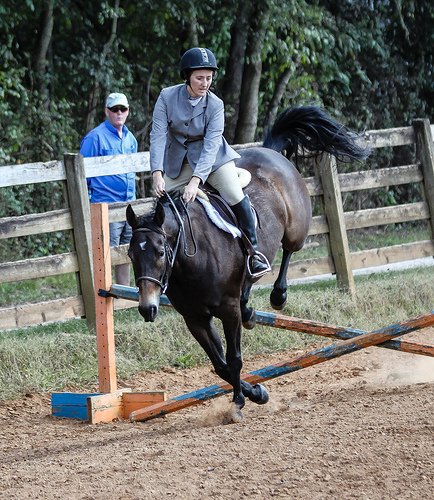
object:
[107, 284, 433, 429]
jump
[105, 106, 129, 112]
dark glasses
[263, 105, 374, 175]
tail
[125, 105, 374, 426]
zebra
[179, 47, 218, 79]
hat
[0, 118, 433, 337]
fence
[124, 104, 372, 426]
horse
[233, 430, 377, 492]
path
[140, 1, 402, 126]
trees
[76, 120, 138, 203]
shirt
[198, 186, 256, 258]
boot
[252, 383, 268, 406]
hooves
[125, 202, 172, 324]
head.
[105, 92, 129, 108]
cap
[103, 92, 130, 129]
head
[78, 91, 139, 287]
man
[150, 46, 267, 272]
girl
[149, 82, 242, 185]
jacket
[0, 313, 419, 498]
ground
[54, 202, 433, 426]
post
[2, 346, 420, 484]
dirt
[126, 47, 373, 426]
competition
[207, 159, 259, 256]
leg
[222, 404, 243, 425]
hoof